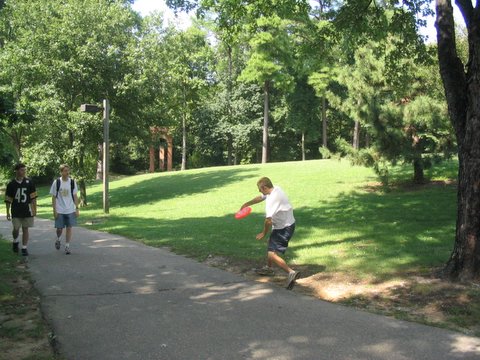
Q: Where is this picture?
A: At a park.